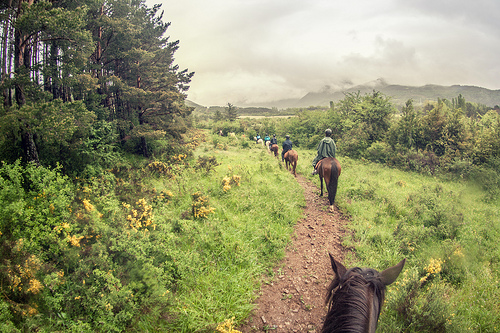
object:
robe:
[312, 137, 336, 166]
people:
[311, 129, 336, 175]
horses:
[269, 143, 279, 159]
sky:
[0, 1, 500, 108]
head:
[324, 129, 332, 137]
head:
[285, 135, 290, 139]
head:
[273, 134, 275, 137]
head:
[265, 133, 268, 136]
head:
[257, 134, 260, 136]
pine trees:
[0, 0, 91, 157]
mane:
[321, 266, 387, 332]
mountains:
[319, 77, 499, 127]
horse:
[314, 156, 341, 205]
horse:
[319, 252, 406, 331]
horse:
[284, 148, 298, 177]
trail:
[293, 207, 326, 322]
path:
[256, 124, 346, 309]